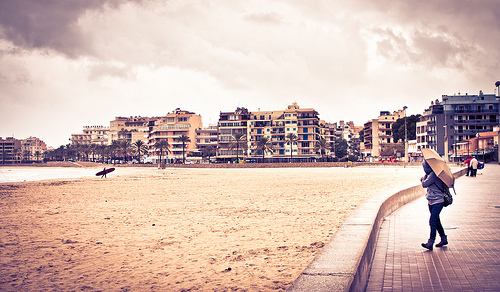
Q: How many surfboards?
A: 1.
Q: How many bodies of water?
A: 1.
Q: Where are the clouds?
A: In the sky.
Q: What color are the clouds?
A: White.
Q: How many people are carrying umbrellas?
A: 1.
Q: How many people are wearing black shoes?
A: 1.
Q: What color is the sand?
A: Brown.